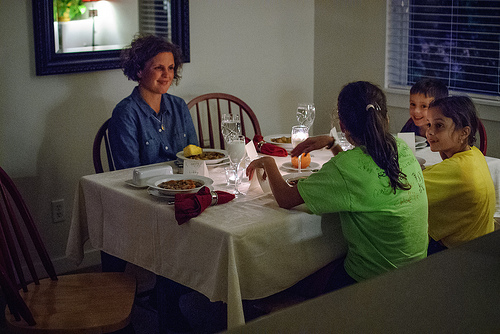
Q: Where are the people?
A: In the dining room.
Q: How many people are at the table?
A: Four.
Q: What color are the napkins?
A: Red.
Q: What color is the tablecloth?
A: White.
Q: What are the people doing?
A: Eating dinner.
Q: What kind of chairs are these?
A: Wooden.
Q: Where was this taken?
A: Dining room.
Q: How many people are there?
A: 4.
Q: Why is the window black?
A: Dark outside.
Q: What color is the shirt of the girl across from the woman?
A: Green.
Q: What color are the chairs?
A: Brown.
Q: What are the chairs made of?
A: Wood.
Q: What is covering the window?
A: Blinds.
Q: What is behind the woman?
A: Mirror.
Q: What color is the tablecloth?
A: White.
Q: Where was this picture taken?
A: Indoors at a table.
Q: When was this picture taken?
A: It is a night time scene.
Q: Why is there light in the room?
A: The lights are on.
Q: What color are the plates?
A: The plates are white.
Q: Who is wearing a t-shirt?
A: The girl.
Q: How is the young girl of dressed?
A: In a t-shirt.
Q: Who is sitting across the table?
A: A woman with curly hair.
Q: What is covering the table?
A: A table cloth.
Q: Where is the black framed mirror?
A: On the wall.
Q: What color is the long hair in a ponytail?
A: Brown.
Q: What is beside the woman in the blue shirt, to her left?
A: An empty chair.